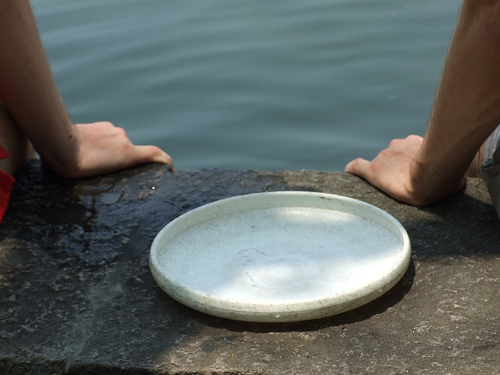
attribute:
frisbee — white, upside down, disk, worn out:
[149, 188, 413, 325]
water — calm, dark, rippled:
[27, 0, 466, 175]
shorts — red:
[0, 137, 19, 224]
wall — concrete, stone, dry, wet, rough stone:
[0, 160, 500, 374]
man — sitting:
[2, 0, 175, 224]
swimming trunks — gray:
[480, 125, 500, 185]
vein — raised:
[474, 95, 499, 125]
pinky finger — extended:
[134, 143, 176, 172]